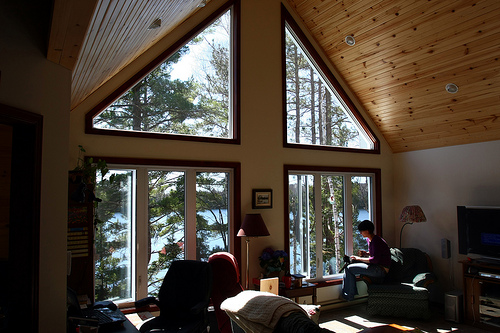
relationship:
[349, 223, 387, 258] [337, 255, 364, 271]
girl with cat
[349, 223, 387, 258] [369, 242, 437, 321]
girl on chair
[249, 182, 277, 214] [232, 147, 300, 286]
picture on wall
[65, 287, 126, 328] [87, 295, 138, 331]
laptop on table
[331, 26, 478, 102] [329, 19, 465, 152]
lights on ceiling